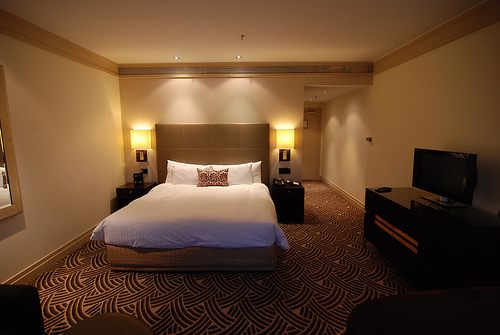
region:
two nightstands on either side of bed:
[93, 109, 317, 281]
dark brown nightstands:
[96, 115, 309, 273]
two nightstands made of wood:
[80, 114, 319, 269]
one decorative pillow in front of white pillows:
[161, 154, 264, 203]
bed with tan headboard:
[96, 107, 304, 266]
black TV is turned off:
[388, 126, 485, 224]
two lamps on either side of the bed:
[89, 110, 312, 280]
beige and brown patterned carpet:
[23, 160, 450, 333]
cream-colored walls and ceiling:
[1, 2, 492, 297]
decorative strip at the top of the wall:
[81, 55, 388, 129]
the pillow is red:
[182, 154, 256, 188]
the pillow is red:
[190, 154, 281, 242]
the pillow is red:
[185, 141, 250, 212]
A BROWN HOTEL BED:
[148, 116, 275, 285]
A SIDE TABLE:
[273, 173, 315, 226]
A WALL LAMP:
[272, 113, 309, 169]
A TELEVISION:
[408, 144, 490, 219]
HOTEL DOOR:
[296, 99, 328, 188]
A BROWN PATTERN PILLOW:
[191, 163, 238, 187]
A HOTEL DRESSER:
[352, 187, 491, 282]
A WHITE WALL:
[25, 76, 92, 255]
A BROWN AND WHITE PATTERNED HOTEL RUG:
[167, 267, 311, 334]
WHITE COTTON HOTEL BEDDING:
[151, 158, 276, 248]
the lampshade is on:
[116, 108, 170, 180]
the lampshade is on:
[115, 98, 206, 219]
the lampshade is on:
[126, 114, 227, 294]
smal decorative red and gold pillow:
[188, 163, 242, 192]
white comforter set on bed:
[123, 159, 304, 259]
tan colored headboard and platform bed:
[145, 113, 294, 263]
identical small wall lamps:
[123, 119, 337, 152]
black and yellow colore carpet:
[59, 283, 214, 318]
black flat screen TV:
[399, 144, 490, 210]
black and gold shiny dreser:
[359, 196, 484, 323]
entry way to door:
[303, 105, 355, 194]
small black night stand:
[269, 182, 314, 229]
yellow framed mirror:
[2, 120, 30, 216]